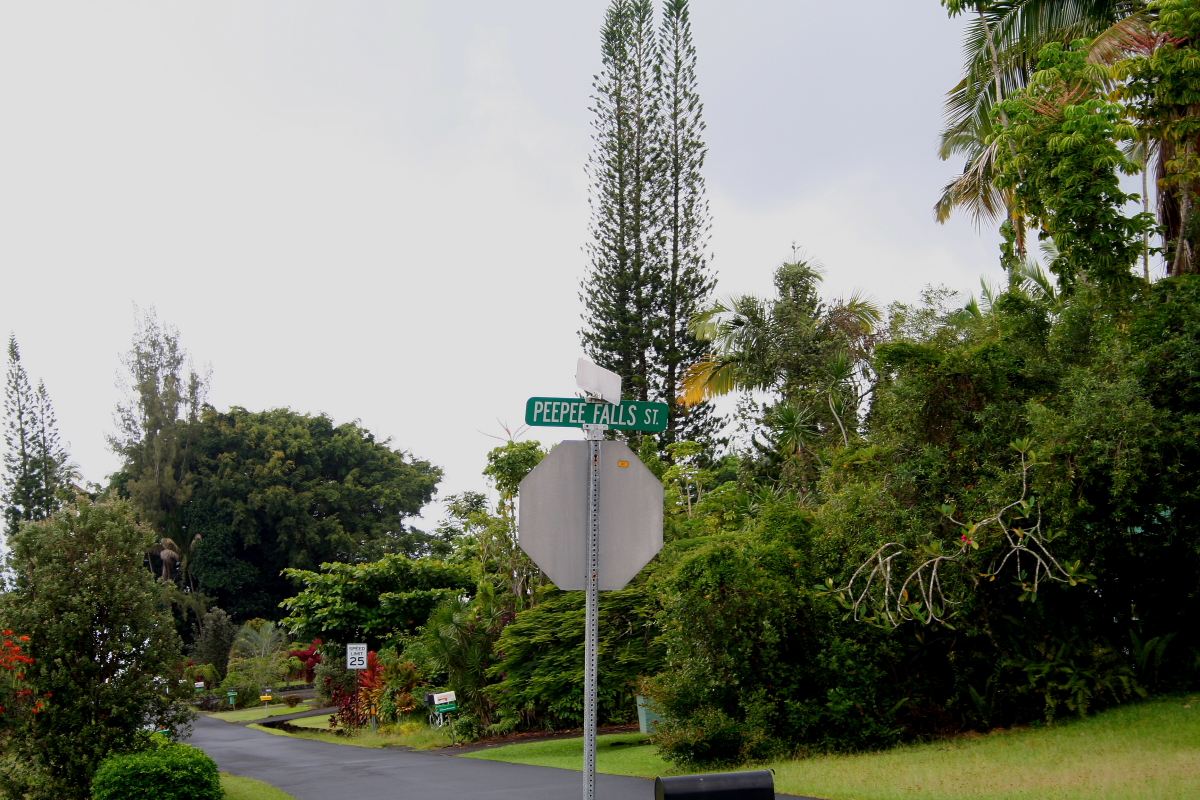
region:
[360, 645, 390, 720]
Red bush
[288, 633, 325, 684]
Red bush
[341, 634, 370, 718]
Street sign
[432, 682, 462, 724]
Street sign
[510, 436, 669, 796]
Street sign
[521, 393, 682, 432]
Sign with a street name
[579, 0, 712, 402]
Tall tree is growing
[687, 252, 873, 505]
Tall tree is growing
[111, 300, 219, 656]
Tall tree is growing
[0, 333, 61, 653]
Tall tree is growing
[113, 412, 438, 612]
large tree is green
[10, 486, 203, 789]
large tree is green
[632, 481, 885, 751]
large tree is green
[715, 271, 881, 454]
large tree is green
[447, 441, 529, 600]
large tree is green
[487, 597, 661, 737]
large tree is green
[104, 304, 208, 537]
large tree is green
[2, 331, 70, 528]
large tree is green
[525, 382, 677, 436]
green and white street sign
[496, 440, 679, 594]
shape is octagon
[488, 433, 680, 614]
Back of stop sign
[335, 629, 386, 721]
Speed limit on sign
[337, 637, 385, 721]
speed limit is 25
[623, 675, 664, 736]
Trash can behind tree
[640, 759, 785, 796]
Black barrel in street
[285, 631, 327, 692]
Red flowering tree behind bush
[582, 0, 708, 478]
Tall tree is green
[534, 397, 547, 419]
A letter on a sign.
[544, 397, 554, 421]
A letter on a sign.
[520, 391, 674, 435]
a green sign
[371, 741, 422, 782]
the road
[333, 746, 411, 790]
the street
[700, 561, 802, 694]
bushes are green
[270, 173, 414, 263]
the sky is grey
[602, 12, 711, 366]
a tall bush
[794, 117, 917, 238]
the sky is grey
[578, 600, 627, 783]
a pole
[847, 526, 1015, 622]
tree branches near the bush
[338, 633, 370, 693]
traffic sign is black and white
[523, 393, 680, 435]
street sign is green and white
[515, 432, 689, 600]
stop sign on the pole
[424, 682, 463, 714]
lawn sign is green and white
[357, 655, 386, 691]
red flowers on the lawn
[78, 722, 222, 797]
green bush on the lawn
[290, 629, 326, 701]
red bush on the lawn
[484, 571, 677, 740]
green bush on the lawn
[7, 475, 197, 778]
green bush on the lawn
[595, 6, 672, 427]
A tree in the woods.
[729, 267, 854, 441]
A tree in the woods.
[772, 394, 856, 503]
A tree in the woods.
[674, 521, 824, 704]
A tree in the woods.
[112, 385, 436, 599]
A tree in the woods.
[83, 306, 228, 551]
A tree in the woods.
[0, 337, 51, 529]
A tree in the woods.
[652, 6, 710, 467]
A tree in the woods.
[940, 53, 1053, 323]
A tree in the woods.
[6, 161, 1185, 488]
The cloudy sky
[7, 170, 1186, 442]
A cloudy sky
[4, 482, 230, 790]
The trees to the left